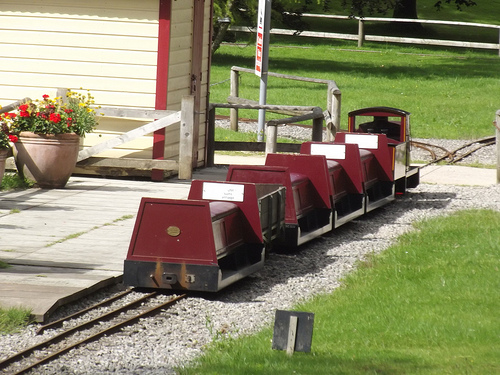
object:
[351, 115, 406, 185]
engine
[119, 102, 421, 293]
train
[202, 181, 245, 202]
sign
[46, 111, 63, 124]
flower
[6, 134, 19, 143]
flower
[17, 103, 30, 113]
flower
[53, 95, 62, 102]
flower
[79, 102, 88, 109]
flower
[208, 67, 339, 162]
fence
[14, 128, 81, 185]
pot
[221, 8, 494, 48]
fence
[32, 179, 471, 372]
path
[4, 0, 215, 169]
house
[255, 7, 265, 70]
sign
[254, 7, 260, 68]
writing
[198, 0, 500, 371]
grass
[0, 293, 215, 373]
ballast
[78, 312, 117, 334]
ties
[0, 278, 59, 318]
concrete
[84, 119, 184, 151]
stick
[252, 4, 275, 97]
sign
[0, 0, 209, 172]
wood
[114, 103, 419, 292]
cart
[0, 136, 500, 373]
tracks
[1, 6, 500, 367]
ground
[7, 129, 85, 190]
planter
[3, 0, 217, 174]
building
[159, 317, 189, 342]
rocks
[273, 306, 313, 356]
sign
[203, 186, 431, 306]
shadow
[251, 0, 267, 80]
sign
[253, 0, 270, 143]
pole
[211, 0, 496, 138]
area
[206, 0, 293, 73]
tree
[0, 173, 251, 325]
deck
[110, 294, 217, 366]
gravel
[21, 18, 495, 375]
garden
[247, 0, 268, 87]
sign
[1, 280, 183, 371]
tracks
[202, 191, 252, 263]
bench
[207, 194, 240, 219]
cushion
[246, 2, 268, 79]
sign